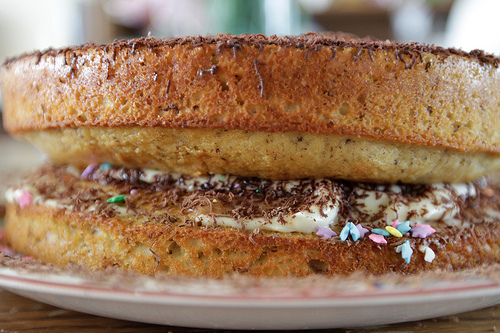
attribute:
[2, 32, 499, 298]
cake — vanilla, sitting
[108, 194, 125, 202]
sprinkles — stars, pink, small, colored, green, food, blue, star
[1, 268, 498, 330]
plate — white, red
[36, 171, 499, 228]
shavings — chocolate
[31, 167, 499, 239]
frosting — white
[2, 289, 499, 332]
table — wooden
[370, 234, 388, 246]
star — pink, purple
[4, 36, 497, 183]
bread — brown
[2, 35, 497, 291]
pastry — chocolate, brown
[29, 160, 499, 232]
filling — white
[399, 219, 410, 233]
flakes — chocolate, food